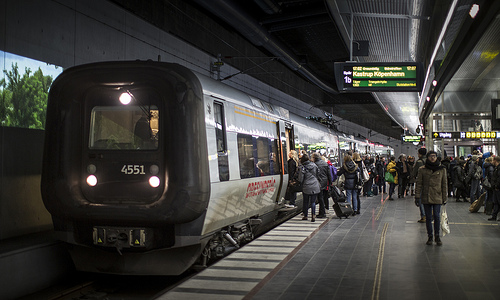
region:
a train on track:
[35, 54, 418, 285]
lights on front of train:
[83, 82, 163, 196]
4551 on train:
[118, 157, 146, 181]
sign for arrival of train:
[338, 58, 498, 143]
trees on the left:
[0, 60, 55, 131]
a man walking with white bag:
[408, 147, 453, 253]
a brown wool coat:
[416, 164, 449, 207]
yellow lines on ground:
[369, 206, 389, 298]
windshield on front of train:
[86, 104, 163, 147]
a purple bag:
[328, 162, 337, 176]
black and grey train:
[47, 60, 397, 270]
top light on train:
[117, 92, 132, 108]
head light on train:
[87, 172, 95, 187]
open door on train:
[276, 122, 296, 203]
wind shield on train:
[91, 105, 158, 152]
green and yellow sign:
[353, 63, 417, 90]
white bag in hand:
[439, 205, 451, 236]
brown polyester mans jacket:
[414, 167, 450, 207]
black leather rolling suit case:
[332, 184, 352, 219]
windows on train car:
[233, 111, 280, 179]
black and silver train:
[93, 92, 330, 245]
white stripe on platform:
[222, 221, 318, 292]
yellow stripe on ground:
[369, 181, 404, 296]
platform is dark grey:
[269, 206, 414, 298]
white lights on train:
[74, 78, 164, 195]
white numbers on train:
[117, 163, 168, 183]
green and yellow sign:
[333, 49, 430, 96]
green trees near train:
[0, 78, 78, 133]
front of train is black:
[33, 60, 214, 284]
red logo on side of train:
[244, 167, 293, 206]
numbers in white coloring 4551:
[120, 163, 146, 178]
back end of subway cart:
[37, 58, 209, 268]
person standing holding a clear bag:
[410, 146, 447, 252]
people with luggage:
[284, 142, 353, 227]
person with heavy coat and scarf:
[410, 142, 455, 256]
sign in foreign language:
[332, 55, 422, 97]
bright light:
[117, 89, 134, 105]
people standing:
[382, 150, 413, 200]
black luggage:
[329, 198, 360, 216]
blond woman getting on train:
[282, 147, 301, 206]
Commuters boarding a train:
[32, 50, 409, 279]